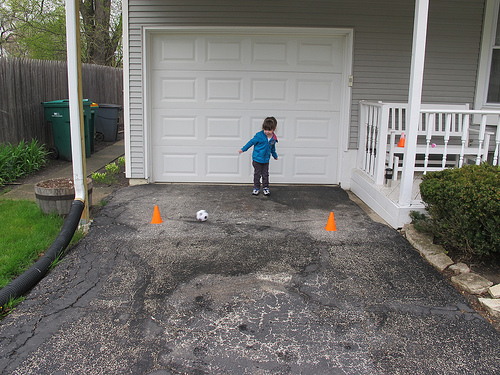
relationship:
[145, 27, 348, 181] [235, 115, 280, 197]
garage door behind boy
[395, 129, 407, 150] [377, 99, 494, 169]
cone on bench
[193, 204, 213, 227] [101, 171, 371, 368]
ball on driveway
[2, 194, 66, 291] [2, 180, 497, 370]
grass next driveway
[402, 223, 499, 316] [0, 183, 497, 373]
stones on right of drive way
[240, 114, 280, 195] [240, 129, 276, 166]
child wearing jacket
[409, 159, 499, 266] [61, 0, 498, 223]
bush in front of house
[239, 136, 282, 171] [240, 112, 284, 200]
jacket on child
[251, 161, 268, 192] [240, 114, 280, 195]
pants on child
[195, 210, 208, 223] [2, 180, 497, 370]
ball on driveway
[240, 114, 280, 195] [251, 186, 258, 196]
child wearing shoe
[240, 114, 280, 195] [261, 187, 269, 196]
child wearing shoe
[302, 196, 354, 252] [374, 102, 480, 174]
cone on bench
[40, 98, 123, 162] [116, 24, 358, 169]
bin beside garage